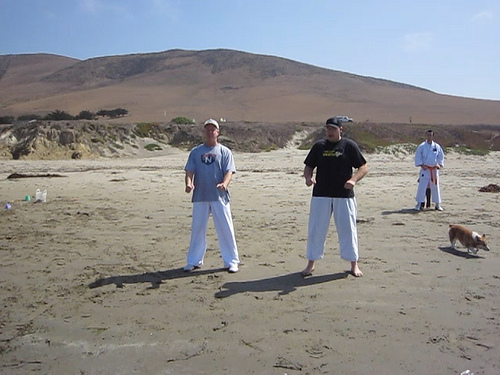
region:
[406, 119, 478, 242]
aman in a karate outfit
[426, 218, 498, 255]
a short brown and white dog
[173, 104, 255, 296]
man with a gray shirt on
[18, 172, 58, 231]
plastic bottles in the sand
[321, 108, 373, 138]
a truck parked on the road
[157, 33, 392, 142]
big dunes of sand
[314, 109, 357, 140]
man wearing a black baseball cap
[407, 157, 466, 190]
an orange belt around man's waist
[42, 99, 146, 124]
trees on the sand dunes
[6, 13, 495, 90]
bright blue sky with one small cloud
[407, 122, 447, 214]
person wearing karate clothing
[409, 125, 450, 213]
karate cloths are white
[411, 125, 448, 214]
red belt on karate clothing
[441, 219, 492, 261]
a white and brown dog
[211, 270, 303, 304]
shadow of a person cast on ground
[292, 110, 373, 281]
man wears white pants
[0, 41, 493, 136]
a brown mountain on the background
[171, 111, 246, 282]
person wears white pants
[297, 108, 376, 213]
person wears black shirt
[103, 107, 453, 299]
people are outdoor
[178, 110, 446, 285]
There are three men in this picture.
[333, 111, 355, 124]
There is a truck on the road.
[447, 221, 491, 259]
There is a dog walking on the sand.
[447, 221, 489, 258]
The dog has short legs and is brown and white.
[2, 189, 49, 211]
There is trash on the sandy shore.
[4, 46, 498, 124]
There is a mountain with a few trees.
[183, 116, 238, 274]
Man is wearing a white baseball cap.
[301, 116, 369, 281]
Man is wearing a black baseball cap.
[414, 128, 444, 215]
Man wearing a karate uniform with an orange belt.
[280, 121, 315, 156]
Path leading from the shore to the road.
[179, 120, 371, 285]
the men on the sand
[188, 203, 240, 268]
the white gii pants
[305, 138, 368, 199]
the black tee shirt on the man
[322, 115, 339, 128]
the black hat on the man head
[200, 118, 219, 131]
the white hat on the mans head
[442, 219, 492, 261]
the dog on the beach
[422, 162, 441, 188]
the red belt on the mans waist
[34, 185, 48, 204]
the white bucket on the beach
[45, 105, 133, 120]
the trees on the side of the hill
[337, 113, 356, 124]
the white truck on the hilltop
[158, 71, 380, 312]
two people standing together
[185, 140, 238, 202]
man wearing grey shirt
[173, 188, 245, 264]
man wearing white pants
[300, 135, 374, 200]
man wearing black shirt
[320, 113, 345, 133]
man wearing black hat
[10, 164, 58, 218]
several bottle on ground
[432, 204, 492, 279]
a dog next to people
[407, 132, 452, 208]
a person wearing a karate outfit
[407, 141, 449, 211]
the outfit is white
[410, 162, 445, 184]
person has red belt